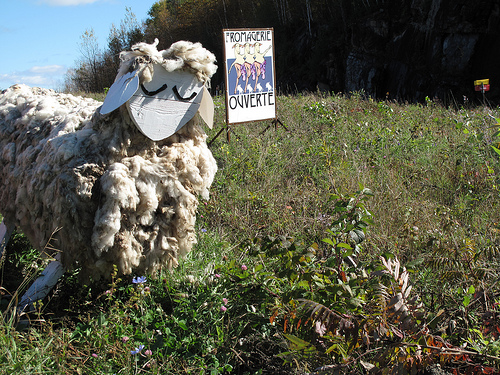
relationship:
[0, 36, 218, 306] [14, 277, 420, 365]
lamb on grass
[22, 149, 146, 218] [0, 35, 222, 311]
fur on sheep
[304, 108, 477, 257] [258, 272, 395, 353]
bush in grass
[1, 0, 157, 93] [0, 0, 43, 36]
clouds in sky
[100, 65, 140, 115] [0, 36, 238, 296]
ear on sheep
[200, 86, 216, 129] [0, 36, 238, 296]
ear on sheep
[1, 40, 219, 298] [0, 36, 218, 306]
wool on lamb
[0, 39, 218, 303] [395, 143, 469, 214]
scarecrow on grass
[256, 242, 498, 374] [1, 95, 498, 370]
leaves on floor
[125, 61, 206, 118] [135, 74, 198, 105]
box has paintings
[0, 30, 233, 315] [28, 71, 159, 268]
body covered by wool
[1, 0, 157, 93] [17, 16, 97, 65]
clouds in sky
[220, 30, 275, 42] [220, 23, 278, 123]
fromagerie on top of sign